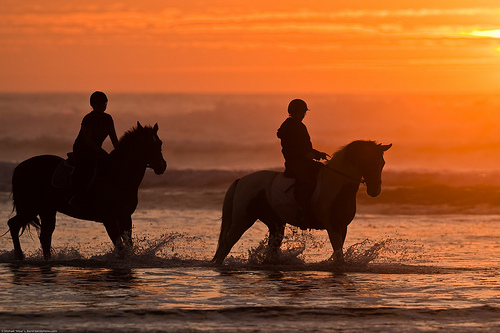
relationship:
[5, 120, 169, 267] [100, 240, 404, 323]
horse in water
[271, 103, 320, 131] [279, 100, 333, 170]
head on person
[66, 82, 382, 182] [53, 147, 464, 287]
people on animals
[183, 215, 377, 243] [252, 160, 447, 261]
legs on horse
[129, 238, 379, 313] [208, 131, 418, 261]
water under horse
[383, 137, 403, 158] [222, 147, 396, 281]
ear on horse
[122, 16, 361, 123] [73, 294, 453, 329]
sky above land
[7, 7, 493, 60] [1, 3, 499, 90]
clouds in sky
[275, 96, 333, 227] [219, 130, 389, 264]
person on horse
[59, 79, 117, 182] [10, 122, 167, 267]
person on horse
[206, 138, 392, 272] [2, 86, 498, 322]
horse splashing in water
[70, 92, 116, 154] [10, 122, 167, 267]
person riding on horse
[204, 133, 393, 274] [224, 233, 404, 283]
horse kick water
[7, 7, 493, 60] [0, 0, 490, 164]
clouds in sky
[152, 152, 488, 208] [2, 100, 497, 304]
waves in water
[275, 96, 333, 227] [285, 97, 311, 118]
person wearing helmet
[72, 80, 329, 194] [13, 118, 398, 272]
people riding horses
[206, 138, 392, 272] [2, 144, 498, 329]
horse in water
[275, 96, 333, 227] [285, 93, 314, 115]
person wearing helmet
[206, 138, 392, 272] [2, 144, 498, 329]
horse splashing water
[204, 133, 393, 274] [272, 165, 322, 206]
horse has saddle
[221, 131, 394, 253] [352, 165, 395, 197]
horse has bridle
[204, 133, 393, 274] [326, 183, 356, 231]
horse has spot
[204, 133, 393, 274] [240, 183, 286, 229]
horse has spot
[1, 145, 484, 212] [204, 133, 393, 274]
waves behind horse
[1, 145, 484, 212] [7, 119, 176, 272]
waves behind horse